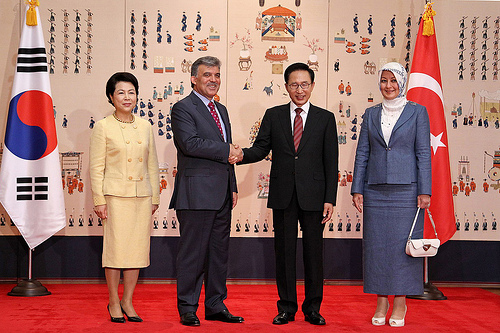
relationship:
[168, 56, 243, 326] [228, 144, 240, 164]
man shaking a hand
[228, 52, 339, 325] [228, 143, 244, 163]
man shaking a hand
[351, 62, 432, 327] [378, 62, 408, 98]
woman wearing a head scarf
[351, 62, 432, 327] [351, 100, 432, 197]
woman wearing a jacket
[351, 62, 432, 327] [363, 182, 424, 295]
woman wearing a skirt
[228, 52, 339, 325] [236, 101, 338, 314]
man has a suit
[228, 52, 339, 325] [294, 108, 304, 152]
man has a tie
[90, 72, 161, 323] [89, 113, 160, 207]
woman has a jacket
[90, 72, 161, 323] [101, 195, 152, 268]
woman has a skirt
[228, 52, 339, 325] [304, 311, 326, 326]
man has a shoe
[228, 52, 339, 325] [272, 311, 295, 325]
man has a shoe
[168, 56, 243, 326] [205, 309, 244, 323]
man has a shoe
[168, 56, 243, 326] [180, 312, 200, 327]
man has a shoe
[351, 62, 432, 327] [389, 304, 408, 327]
woman has a shoe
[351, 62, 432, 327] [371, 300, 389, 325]
woman has a shoe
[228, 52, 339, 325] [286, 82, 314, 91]
man wears glasses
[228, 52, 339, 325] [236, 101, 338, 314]
man wears a suit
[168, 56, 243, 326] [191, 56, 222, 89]
man has hair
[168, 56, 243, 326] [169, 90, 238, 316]
man wearing a suit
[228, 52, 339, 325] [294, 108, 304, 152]
man wears a tie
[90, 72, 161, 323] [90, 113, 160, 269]
woman wearing an outfit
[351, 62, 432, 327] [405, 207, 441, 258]
woman holding purse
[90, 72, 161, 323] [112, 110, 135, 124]
woman wears a necklace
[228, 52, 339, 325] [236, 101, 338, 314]
man wearing a suit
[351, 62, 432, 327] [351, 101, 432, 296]
woman wearing an outfit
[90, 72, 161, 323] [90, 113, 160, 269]
woman wears an outfit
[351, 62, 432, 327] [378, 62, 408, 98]
woman wears a head scarf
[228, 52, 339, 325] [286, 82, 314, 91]
man wearing glasses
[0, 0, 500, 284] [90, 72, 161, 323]
wall behind woman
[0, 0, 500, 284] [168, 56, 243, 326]
wall behind man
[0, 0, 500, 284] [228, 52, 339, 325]
wall behind man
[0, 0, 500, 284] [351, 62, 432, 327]
wall behind woman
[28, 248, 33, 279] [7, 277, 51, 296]
flag pole in holder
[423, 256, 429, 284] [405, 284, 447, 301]
flag pole in stand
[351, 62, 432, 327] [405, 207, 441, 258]
woman holds a purse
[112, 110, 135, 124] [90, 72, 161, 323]
necklace on woman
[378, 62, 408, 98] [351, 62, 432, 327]
head scarf on woman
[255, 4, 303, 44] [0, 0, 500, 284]
drawing on wall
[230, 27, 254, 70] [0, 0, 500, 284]
drawing on wall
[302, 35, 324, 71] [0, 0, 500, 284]
drawing on wall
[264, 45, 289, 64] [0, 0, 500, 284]
drawing on wall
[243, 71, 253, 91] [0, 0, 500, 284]
drawing on wall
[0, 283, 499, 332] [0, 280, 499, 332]
carpet on floor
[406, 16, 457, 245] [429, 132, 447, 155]
flag has a star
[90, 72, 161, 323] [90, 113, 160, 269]
woman in an outfit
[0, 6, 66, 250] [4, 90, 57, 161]
flag has a circle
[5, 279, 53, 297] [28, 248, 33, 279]
bottom of flag pole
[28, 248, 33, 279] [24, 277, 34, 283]
flag pole has holder